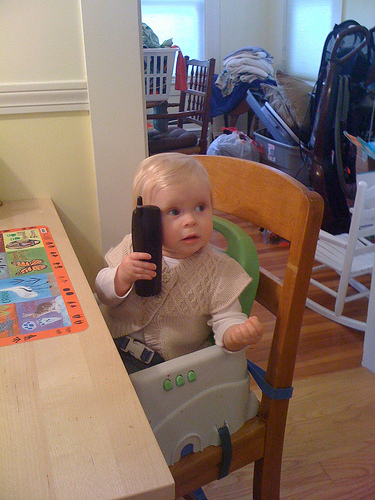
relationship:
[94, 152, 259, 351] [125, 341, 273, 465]
baby in seat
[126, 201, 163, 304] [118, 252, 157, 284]
phone in hand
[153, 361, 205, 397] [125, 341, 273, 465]
buttons on seat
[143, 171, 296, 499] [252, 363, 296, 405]
chair with strap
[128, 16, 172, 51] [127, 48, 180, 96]
laundry in basket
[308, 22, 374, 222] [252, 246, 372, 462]
vacuum on floor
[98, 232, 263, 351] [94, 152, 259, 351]
shirt on baby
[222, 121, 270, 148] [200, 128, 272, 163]
ties on bag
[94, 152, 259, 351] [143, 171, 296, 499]
baby in chair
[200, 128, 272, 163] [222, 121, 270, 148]
bag has ties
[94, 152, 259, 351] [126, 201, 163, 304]
baby holding phone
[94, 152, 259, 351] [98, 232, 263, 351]
baby wearing shirt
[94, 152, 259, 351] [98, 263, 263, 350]
baby wearing shirt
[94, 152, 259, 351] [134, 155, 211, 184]
baby with hair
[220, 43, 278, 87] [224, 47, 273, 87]
clothes in pile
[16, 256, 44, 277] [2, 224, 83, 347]
butterfly on mat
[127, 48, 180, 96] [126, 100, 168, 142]
basket on table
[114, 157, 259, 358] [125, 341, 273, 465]
baby in seat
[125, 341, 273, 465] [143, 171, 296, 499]
seat on chair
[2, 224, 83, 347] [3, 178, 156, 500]
mat on table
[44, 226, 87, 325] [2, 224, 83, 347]
border on mat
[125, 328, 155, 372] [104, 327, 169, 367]
buckle around waist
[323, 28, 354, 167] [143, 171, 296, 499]
rail of chair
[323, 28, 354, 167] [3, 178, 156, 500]
rail behind table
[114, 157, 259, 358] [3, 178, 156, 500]
baby at table